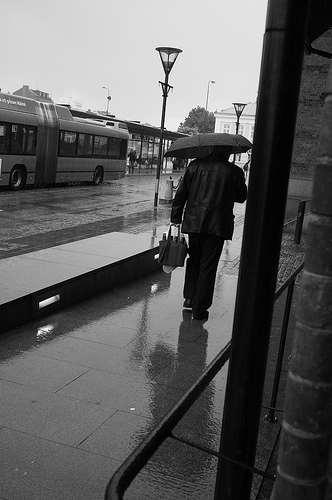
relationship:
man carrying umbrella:
[167, 134, 249, 321] [159, 132, 253, 159]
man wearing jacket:
[167, 134, 249, 321] [166, 152, 248, 240]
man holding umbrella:
[167, 134, 249, 321] [159, 132, 253, 159]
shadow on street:
[144, 318, 222, 490] [5, 226, 311, 491]